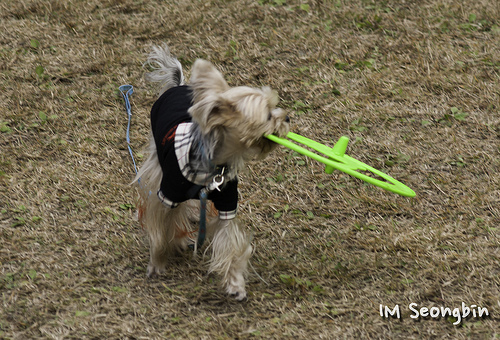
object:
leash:
[118, 84, 227, 251]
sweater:
[149, 85, 238, 220]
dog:
[129, 40, 292, 301]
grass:
[1, 1, 498, 340]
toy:
[262, 130, 417, 198]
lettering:
[378, 301, 489, 326]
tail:
[140, 42, 185, 95]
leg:
[206, 207, 254, 304]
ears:
[188, 97, 238, 136]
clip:
[208, 166, 225, 191]